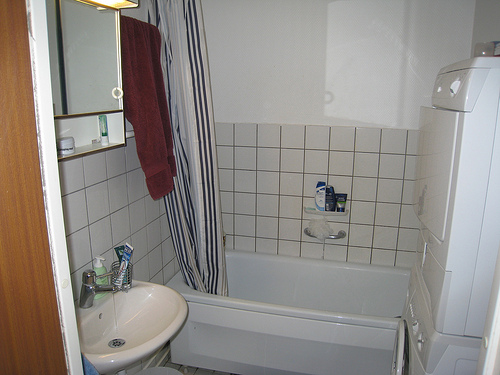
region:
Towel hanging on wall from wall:
[116, 10, 181, 202]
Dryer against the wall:
[411, 56, 498, 341]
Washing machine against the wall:
[380, 254, 499, 374]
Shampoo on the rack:
[302, 174, 329, 217]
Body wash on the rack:
[326, 186, 348, 213]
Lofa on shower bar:
[300, 216, 357, 251]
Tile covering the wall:
[204, 115, 416, 271]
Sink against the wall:
[64, 256, 204, 372]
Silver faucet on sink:
[72, 264, 119, 316]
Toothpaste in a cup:
[111, 233, 136, 293]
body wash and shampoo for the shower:
[313, 176, 350, 214]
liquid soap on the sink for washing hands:
[90, 253, 110, 289]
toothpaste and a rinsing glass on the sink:
[108, 242, 139, 291]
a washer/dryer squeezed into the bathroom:
[391, 47, 496, 374]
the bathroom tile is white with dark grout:
[215, 120, 415, 267]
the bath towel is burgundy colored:
[121, 13, 180, 202]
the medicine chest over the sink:
[48, 0, 133, 162]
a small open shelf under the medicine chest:
[52, 108, 129, 158]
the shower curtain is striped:
[145, 1, 233, 297]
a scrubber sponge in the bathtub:
[303, 215, 336, 241]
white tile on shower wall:
[324, 123, 357, 155]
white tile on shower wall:
[303, 123, 334, 150]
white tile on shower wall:
[279, 124, 306, 153]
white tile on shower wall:
[254, 122, 281, 147]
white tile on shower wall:
[231, 120, 259, 150]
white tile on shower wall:
[231, 142, 259, 174]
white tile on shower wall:
[233, 166, 258, 196]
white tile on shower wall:
[230, 188, 259, 217]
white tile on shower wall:
[230, 209, 257, 242]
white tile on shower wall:
[254, 214, 277, 242]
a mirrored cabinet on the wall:
[49, 0, 123, 120]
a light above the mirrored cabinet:
[75, 0, 139, 12]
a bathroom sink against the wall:
[72, 242, 189, 374]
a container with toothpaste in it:
[109, 242, 136, 290]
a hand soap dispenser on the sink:
[94, 252, 109, 295]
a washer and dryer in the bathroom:
[391, 49, 498, 373]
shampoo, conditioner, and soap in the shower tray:
[311, 180, 350, 213]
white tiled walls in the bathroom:
[53, 118, 433, 303]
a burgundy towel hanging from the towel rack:
[119, 13, 179, 202]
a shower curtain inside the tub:
[146, 0, 228, 295]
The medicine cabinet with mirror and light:
[43, 0, 143, 160]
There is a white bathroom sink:
[69, 245, 190, 372]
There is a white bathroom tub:
[166, 249, 409, 373]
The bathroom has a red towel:
[121, 16, 178, 201]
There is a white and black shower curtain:
[146, 0, 229, 299]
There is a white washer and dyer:
[393, 55, 497, 374]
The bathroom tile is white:
[49, 120, 419, 372]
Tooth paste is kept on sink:
[113, 243, 133, 290]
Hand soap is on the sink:
[92, 254, 108, 292]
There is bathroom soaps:
[306, 181, 351, 215]